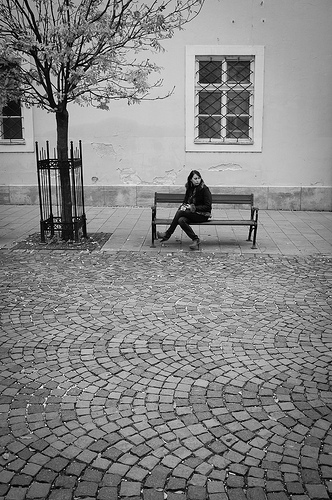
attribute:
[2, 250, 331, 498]
street — black, paved, ground, brick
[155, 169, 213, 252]
lady — waiting, seated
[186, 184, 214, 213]
jacket — black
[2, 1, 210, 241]
tree — small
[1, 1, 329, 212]
wall — chipped, cracked, large, damaged, concrete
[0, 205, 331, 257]
sidewalk — brick, paved